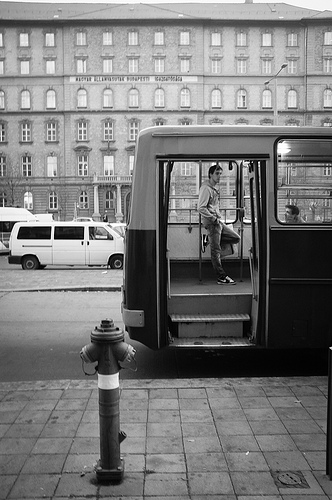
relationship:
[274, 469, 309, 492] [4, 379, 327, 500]
square iron gate seen on ground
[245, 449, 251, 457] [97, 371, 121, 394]
small piece of paper is white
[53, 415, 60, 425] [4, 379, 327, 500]
black spot seen on ground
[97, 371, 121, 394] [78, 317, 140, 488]
white area seen on fire hydrant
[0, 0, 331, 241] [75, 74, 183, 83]
apartment building has a it's name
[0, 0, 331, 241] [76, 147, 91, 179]
building has a large window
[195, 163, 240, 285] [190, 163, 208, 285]
man against post on bus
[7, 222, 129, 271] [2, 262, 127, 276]
large white van seen parked in spot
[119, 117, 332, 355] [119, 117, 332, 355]
bus has a large bus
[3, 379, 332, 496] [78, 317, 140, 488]
sidewalk has a large fire hydrant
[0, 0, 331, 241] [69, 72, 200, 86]
building has written on it it's name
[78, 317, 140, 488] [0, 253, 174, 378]
fire hydrant positioned on city street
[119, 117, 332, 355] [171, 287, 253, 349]
bus has several steps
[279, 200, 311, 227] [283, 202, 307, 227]
man seen on bus man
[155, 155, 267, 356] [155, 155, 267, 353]
door on bus door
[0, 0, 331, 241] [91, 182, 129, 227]
building has in front big pillars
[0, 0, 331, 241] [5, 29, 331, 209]
building has a ton of windows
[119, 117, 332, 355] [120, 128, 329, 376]
bus seen at bus stop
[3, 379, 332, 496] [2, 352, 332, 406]
sidewalk seen beside the bus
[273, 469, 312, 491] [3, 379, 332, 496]
drain hole seen on the sidewalk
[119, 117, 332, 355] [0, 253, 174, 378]
bus traveling on city street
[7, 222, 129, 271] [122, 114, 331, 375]
white van parked beside the bus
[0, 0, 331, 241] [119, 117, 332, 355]
large building on or side bus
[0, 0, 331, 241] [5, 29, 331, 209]
large building that has a lot of windows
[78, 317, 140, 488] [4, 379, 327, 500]
fire hydrant on city street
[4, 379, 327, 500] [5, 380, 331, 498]
city street made up of cement tiles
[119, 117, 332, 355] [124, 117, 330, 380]
bus stopped at a stop waiting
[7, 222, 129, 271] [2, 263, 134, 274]
white mini van parked on city street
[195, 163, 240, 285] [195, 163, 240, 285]
man on city bus man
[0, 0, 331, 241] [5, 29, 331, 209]
city building has a lot of arched windows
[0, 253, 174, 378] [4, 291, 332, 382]
city street has been paved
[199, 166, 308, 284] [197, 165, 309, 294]
two men are seen on bus talking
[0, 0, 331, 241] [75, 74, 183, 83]
building has its name written it's name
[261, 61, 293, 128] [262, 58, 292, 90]
light pole has a light on it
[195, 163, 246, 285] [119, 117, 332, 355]
man on bus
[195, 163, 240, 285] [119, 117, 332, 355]
man standing on bus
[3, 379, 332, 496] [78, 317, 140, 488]
sidewalk has a fire hydrant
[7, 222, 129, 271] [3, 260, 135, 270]
large white van on road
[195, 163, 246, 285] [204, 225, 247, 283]
man leaning on a pole wearing jeans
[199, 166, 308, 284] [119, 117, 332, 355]
two men are seen on bus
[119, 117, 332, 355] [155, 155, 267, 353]
bus seen on road door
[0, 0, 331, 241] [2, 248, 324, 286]
large building sitting on side of the road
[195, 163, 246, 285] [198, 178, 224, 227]
man on bus wearing sweatshirt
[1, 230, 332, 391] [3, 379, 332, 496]
two lanes are separated by sidewalk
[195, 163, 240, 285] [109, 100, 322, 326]
man leaning on bus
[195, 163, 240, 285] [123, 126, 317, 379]
man standing in bus